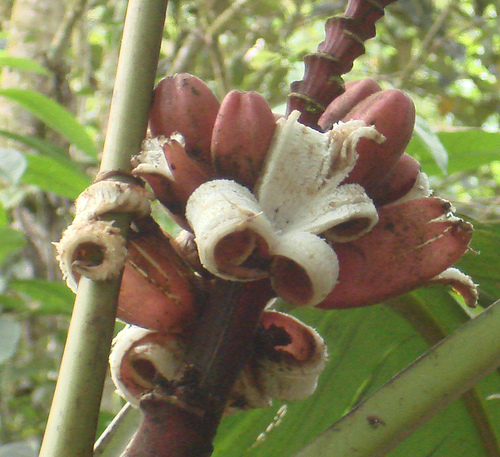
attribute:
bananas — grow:
[64, 72, 428, 419]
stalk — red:
[118, 0, 392, 455]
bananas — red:
[84, 116, 344, 396]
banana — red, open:
[147, 71, 221, 176]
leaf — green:
[8, 59, 88, 226]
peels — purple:
[168, 149, 365, 304]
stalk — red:
[273, 15, 389, 132]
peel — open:
[213, 129, 358, 277]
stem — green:
[40, 1, 170, 453]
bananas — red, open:
[96, 72, 489, 412]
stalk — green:
[40, 0, 167, 454]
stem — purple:
[122, 1, 384, 455]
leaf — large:
[1, 88, 102, 159]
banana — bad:
[145, 69, 215, 167]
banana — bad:
[332, 94, 414, 184]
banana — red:
[291, 191, 488, 308]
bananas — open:
[84, 57, 455, 415]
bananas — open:
[90, 60, 482, 328]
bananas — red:
[57, 46, 467, 404]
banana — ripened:
[197, 107, 466, 407]